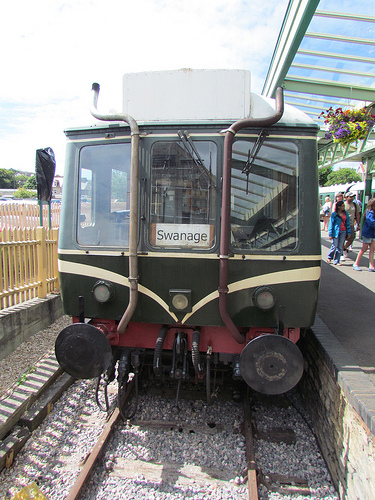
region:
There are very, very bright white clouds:
[217, 13, 230, 37]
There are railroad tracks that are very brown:
[96, 419, 107, 450]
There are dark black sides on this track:
[349, 392, 368, 419]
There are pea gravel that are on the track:
[186, 443, 201, 459]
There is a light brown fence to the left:
[6, 226, 35, 280]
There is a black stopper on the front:
[256, 329, 304, 392]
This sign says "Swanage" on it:
[155, 215, 218, 273]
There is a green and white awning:
[289, 15, 314, 69]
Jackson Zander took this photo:
[106, 103, 292, 416]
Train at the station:
[24, 15, 371, 405]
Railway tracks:
[75, 391, 270, 496]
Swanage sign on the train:
[135, 213, 229, 264]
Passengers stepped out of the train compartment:
[276, 145, 374, 262]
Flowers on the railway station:
[302, 88, 371, 149]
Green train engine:
[40, 83, 321, 329]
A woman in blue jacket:
[324, 184, 355, 268]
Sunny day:
[6, 54, 203, 262]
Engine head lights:
[80, 270, 316, 339]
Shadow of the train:
[282, 198, 374, 365]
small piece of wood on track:
[120, 459, 232, 485]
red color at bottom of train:
[78, 312, 292, 356]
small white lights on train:
[87, 279, 285, 317]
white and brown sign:
[133, 212, 222, 253]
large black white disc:
[225, 327, 318, 397]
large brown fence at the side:
[11, 221, 45, 301]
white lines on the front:
[64, 258, 316, 312]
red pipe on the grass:
[204, 86, 242, 351]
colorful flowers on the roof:
[318, 103, 365, 146]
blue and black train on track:
[40, 80, 374, 379]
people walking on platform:
[320, 180, 374, 265]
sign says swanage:
[143, 217, 209, 260]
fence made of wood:
[0, 217, 72, 289]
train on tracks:
[3, 39, 336, 499]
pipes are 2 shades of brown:
[108, 128, 273, 325]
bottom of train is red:
[75, 301, 287, 379]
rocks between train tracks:
[44, 387, 287, 496]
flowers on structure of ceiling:
[312, 92, 373, 139]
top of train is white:
[119, 61, 295, 148]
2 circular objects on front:
[32, 292, 333, 439]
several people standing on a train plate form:
[301, 173, 373, 272]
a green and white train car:
[23, 108, 329, 498]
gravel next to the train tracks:
[41, 403, 103, 478]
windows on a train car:
[60, 134, 314, 279]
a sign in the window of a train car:
[126, 219, 225, 254]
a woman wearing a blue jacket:
[328, 197, 352, 252]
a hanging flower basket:
[318, 103, 370, 148]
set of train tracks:
[59, 429, 305, 490]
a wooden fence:
[0, 215, 57, 310]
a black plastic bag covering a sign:
[25, 137, 61, 218]